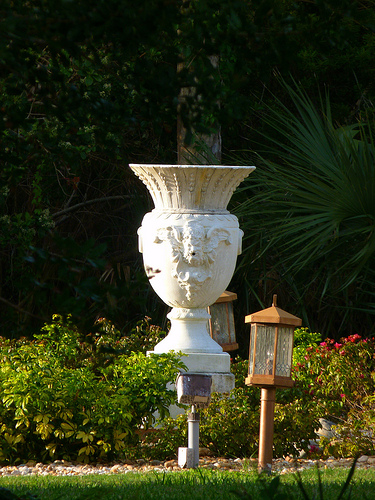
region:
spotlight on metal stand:
[171, 371, 212, 468]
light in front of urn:
[244, 293, 300, 475]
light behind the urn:
[207, 290, 239, 351]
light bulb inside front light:
[265, 343, 275, 357]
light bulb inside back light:
[211, 311, 223, 332]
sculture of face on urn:
[181, 221, 204, 265]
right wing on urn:
[206, 227, 232, 254]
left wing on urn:
[153, 225, 182, 264]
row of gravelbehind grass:
[1, 455, 374, 476]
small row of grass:
[0, 467, 373, 499]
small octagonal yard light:
[236, 251, 305, 467]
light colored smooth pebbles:
[6, 452, 175, 480]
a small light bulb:
[258, 330, 274, 366]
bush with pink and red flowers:
[304, 325, 359, 393]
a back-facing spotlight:
[155, 353, 217, 477]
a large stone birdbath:
[109, 130, 239, 415]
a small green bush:
[8, 313, 168, 458]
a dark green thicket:
[16, 195, 352, 460]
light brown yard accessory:
[237, 285, 300, 471]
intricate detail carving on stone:
[156, 204, 238, 334]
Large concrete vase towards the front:
[120, 141, 263, 383]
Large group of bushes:
[7, 325, 150, 456]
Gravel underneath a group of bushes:
[16, 455, 126, 475]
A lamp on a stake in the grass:
[243, 298, 295, 473]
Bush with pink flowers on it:
[304, 322, 372, 410]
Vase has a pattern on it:
[154, 220, 239, 295]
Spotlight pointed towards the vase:
[159, 351, 227, 487]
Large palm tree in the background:
[242, 126, 370, 253]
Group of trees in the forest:
[9, 66, 115, 298]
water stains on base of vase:
[194, 344, 244, 401]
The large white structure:
[121, 152, 256, 424]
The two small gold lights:
[206, 288, 303, 476]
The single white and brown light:
[169, 367, 213, 466]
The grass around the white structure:
[0, 465, 373, 498]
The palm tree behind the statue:
[180, 79, 366, 336]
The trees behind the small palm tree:
[0, 1, 372, 320]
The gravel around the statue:
[1, 454, 373, 475]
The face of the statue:
[178, 221, 209, 267]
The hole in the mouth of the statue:
[186, 248, 199, 259]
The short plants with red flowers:
[1, 307, 373, 458]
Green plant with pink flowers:
[310, 330, 371, 393]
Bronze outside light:
[230, 278, 307, 475]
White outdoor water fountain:
[113, 86, 261, 400]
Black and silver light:
[166, 369, 214, 477]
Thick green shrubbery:
[6, 332, 146, 467]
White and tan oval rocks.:
[62, 459, 138, 473]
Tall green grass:
[135, 474, 192, 498]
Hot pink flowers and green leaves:
[297, 330, 373, 440]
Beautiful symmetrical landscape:
[9, 4, 358, 482]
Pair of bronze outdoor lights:
[212, 293, 299, 478]